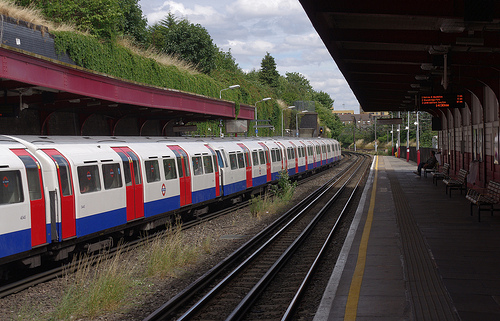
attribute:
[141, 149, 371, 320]
tracks — brown, silver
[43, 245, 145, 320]
grass — green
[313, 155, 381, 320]
lines — white, yellow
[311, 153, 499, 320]
platform — gray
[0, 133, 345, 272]
train — red, white, & blue, long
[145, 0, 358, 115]
clouds — white, gray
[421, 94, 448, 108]
lettering — orange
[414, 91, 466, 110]
sign — black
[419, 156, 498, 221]
benches — tan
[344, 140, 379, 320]
line — yellow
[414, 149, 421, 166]
base of pole — red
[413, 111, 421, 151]
pole — silver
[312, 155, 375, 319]
line — white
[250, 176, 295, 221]
grass — tall, green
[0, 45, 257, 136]
overhang — red, metal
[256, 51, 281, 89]
tree — green, tall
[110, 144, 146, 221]
door — red